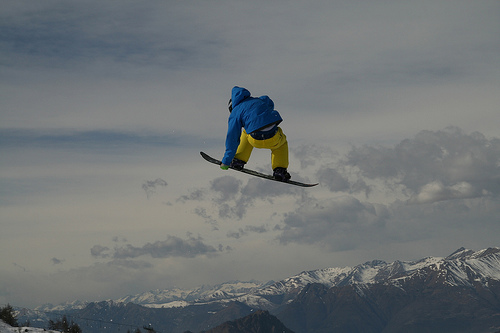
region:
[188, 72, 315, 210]
man doing tricks in air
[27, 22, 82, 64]
white clouds in blue sky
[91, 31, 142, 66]
white clouds in blue sky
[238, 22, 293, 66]
white clouds in blue sky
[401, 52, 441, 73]
white clouds in blue sky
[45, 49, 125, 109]
white clouds in blue sky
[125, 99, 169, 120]
white clouds in blue sky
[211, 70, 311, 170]
this is a person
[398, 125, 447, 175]
this is a cloud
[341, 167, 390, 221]
this is a cloud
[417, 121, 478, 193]
this is a cloud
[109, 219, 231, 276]
this is a cloud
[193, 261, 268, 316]
this is a mountain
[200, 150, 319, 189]
Black snow board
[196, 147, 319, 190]
Man holding a black snowboard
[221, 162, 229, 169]
Green glove on a man's hand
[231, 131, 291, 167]
Snow boarder wearing yellow pants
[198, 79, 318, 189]
Snow boarder in the air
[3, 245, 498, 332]
Mountains beneath a snow boarder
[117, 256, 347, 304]
Snow on the mountain tops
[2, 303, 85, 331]
Trees in the mountains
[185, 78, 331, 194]
a snowboarder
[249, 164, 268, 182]
a snow board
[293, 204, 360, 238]
the cloud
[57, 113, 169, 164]
clouds in the sky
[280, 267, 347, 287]
the snow on the mountains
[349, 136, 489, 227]
the clouds are grey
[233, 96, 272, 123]
a jacket the person is wearing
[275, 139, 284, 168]
yellow pants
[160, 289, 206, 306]
the snow is white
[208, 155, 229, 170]
person is holding the snowboard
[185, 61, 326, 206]
man doing tricks on snow board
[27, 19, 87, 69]
white clouds in blue sky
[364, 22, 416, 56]
white clouds in blue sky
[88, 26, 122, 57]
white clouds in blue sky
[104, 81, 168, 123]
white clouds in blue sky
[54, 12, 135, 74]
white clouds in blue sky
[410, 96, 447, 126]
white clouds in blue sky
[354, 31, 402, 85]
white clouds in blue sky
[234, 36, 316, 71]
white clouds in blue sky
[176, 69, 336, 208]
man is in the air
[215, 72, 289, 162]
man wearing a blue hoodie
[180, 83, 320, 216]
man doing a trick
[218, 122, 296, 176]
man wearing yellow pants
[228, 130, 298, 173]
man has knees bent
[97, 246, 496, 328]
mountains in the distance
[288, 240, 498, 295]
snow on the mountain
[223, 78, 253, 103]
hood on the jacket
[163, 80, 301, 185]
a person on a snowboard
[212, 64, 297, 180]
a person in the air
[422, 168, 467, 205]
a white fluffy cloud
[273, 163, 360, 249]
a white fluffy cloud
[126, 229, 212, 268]
a white fluffy cloud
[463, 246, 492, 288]
snow on the mountain